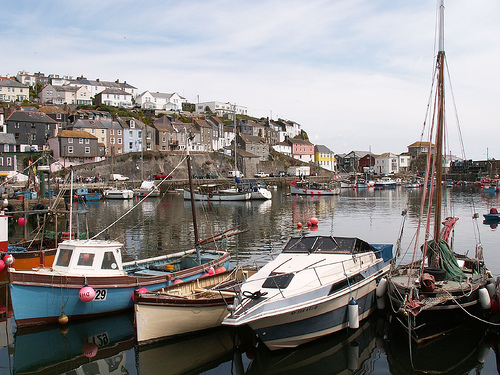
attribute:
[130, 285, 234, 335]
boat — small, tan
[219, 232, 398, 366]
boat — blue and white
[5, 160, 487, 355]
boats — empty, docked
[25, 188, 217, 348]
boat — blue and brown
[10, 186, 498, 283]
water surface — calm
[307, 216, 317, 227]
fishing ball — floating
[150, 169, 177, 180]
truck — red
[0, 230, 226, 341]
boat — blue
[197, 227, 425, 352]
boat — anchored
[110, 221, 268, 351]
boat — anchored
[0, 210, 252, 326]
boat — anchored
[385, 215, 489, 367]
boat — blue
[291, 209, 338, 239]
fishing ball — floating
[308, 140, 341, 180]
building — yellow, white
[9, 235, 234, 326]
boat — blue and brown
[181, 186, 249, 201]
long boat — white